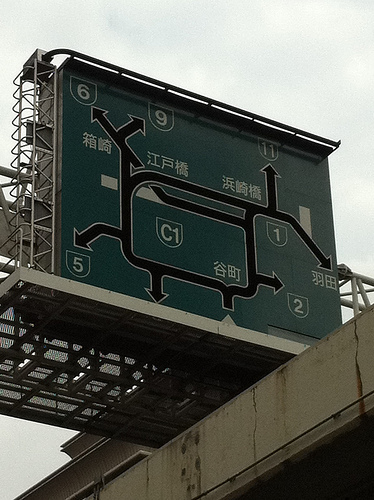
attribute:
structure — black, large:
[3, 50, 368, 447]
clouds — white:
[3, 1, 372, 275]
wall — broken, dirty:
[96, 302, 371, 499]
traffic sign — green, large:
[59, 63, 347, 338]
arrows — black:
[86, 103, 113, 126]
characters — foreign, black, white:
[69, 72, 340, 319]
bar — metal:
[43, 46, 341, 149]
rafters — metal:
[8, 58, 56, 278]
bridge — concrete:
[81, 313, 367, 499]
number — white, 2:
[285, 297, 317, 317]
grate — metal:
[0, 278, 312, 429]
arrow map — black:
[72, 104, 334, 310]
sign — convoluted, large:
[41, 49, 358, 345]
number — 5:
[66, 250, 92, 277]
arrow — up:
[260, 160, 283, 179]